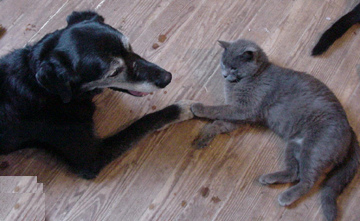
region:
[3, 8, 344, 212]
spots on wooden floor of strips of wood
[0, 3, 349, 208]
dog and cat lying on floor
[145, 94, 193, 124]
paws of dog and cat touching gray object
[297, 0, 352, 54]
straight tail of black cat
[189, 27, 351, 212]
gray cat lying on her side with head lifted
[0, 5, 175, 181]
black dog lying on her stomach with head lifted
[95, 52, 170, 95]
edge of pink tongue in open mouth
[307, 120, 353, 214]
tail along body and then flaring out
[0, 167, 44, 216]
surface and end of flooring slats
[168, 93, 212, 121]
Pair of paws touching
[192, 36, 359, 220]
Cat laying on the floor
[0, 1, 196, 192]
Dog laying on the floor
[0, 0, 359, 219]
Brown colored plastic floor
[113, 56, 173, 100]
Mouth of dog slightly open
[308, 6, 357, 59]
Black colored long tail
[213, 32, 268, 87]
Head of a cat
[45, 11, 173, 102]
Head of a dog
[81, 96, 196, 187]
Black leg of a dog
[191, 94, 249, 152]
Pair of grey legs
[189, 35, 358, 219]
The cat is gray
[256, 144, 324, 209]
Two legs of a cat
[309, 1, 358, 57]
Black tail of an animal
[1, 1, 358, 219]
A dog and cat lying on the floor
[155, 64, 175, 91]
Black nose of a dog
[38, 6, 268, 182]
Dog and cat are touching paws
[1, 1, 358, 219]
A brown and wooden floor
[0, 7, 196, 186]
A dog is black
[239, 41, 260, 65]
An ear of a cat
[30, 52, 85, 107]
A black ear of a dog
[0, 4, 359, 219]
a cat and dog being friendly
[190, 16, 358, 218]
a grey cat relaxing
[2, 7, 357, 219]
a cat and dog relaxing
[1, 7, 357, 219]
a cat and dog relaxing with each other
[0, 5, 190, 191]
a dog with white whiskers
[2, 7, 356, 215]
dog and cat touching paws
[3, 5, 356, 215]
a dog and a cat touching each other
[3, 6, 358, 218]
a dog and a cat touching each other's paws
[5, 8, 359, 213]
a cat exploring a dog's paw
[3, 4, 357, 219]
a black dog playing with a gray cat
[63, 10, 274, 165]
Cat and a dog touching paws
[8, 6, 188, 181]
Dog lying on a wood floor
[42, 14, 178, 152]
Black dog lying on the floor panting.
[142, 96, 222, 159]
Cat and dog holding hands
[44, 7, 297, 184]
Gray cat looking at black dog.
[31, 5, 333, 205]
Cat and dog lying together on the floor.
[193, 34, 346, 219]
Gray cat lying down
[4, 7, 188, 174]
Dog resting on the floor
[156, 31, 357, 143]
a cat on the floor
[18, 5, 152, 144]
a dog on the floor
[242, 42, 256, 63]
an ear on the cat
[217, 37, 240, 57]
an ear on the cat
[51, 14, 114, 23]
an ear on the dog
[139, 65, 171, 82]
a nose on the dog